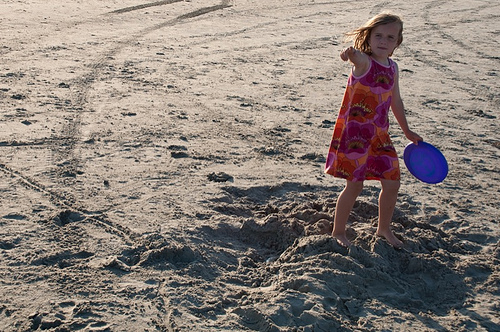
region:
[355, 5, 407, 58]
head of a person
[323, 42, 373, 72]
arm of a person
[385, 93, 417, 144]
arm of a person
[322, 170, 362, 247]
leg of a person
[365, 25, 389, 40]
eye of a person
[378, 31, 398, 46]
eye of a person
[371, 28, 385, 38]
an eye of a person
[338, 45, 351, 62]
finger of a person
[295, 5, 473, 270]
young girl with a blue frisbee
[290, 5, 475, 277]
a young girl with a blue frisbee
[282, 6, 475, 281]
a young girl with a blue frisbee pointing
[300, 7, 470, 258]
a young girl holding a blue frisbee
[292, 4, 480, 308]
a young girl pointing with one hand and holding a frisbee in the other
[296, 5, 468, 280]
a young girl playing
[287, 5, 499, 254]
young girl playing in the sand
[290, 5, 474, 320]
a young girl playing in the sand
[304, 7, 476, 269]
a girl with a frisbee in her left hand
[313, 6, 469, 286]
a girl pointing with her right hand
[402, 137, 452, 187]
Girl holding a frisbee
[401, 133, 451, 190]
Girl is holding a frisbee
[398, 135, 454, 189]
Girl holding a blue frisbee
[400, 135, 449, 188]
Girl is holding a blue frisbee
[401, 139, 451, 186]
Child holding a frisbee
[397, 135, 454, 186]
Child is holding a frisbee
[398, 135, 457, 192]
Child holding a blue frisbee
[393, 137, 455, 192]
Child holding a blue frisbee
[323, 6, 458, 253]
Girl on the sand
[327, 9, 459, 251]
Girl is on the sand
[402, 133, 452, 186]
a girl with a blue frisbee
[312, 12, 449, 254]
a girl holding a blue frisbee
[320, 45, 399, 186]
a girl in an orange and pink dress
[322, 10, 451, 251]
a girl with a frisbee on the beach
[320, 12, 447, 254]
a girl holding a frisbee on the beach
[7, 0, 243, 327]
the tracks of a tire on the beach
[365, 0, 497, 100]
the tracks of a tire on the beach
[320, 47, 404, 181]
a girl in a flower dress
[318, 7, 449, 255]
a girl pointing at something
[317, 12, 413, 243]
this is a child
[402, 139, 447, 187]
this is a frisbee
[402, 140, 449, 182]
the frisbee is blue in color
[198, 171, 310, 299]
this is the beach sand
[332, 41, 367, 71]
this is the hand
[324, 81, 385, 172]
this is the dress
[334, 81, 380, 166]
the dress are red in color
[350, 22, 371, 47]
this is the hair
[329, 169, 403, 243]
these are the legs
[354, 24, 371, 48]
the hair is long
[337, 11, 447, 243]
a girl is pointing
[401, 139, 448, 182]
the frisbee is blue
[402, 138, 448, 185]
medium blue flying disk toy held by girl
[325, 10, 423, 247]
young blonde girl standing in sand pointing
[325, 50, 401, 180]
orange pink and red dress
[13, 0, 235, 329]
large vehical tracks in sand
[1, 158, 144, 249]
small vehical track in sand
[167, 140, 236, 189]
shoe prints in sand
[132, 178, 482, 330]
area of dug and mounded sand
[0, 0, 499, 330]
sand covered ground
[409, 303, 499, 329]
shadow of girls legs on sand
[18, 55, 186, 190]
Large body of sand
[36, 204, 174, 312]
Large body of sand